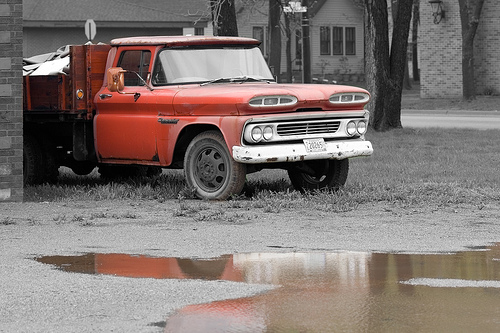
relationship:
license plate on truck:
[299, 136, 334, 156] [20, 26, 393, 218]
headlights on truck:
[239, 120, 368, 142] [20, 26, 393, 218]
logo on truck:
[152, 113, 188, 127] [20, 26, 393, 218]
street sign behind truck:
[80, 16, 101, 41] [20, 26, 393, 218]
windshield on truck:
[150, 40, 277, 88] [20, 26, 393, 218]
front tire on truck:
[181, 126, 246, 203] [20, 26, 393, 218]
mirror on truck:
[103, 65, 155, 101] [20, 26, 393, 218]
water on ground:
[308, 257, 378, 315] [7, 202, 500, 332]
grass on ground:
[398, 124, 499, 204] [7, 202, 500, 332]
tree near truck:
[360, 2, 423, 133] [20, 26, 393, 218]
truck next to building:
[20, 26, 393, 218] [413, 2, 499, 104]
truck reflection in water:
[93, 254, 310, 283] [308, 257, 378, 315]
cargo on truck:
[25, 41, 71, 74] [20, 26, 393, 218]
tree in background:
[360, 2, 423, 133] [20, 2, 500, 46]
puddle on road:
[260, 248, 437, 327] [7, 202, 500, 332]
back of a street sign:
[91, 27, 96, 33] [81, 19, 97, 41]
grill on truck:
[276, 119, 343, 135] [20, 26, 393, 218]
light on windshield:
[172, 63, 199, 77] [150, 40, 277, 88]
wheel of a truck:
[289, 155, 354, 193] [20, 26, 393, 218]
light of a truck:
[345, 118, 358, 135] [20, 26, 393, 218]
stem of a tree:
[365, 68, 411, 133] [360, 2, 423, 133]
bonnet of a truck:
[102, 29, 266, 50] [20, 26, 393, 218]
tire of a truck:
[181, 126, 246, 203] [20, 26, 393, 218]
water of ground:
[308, 257, 378, 315] [7, 202, 500, 332]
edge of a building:
[455, 13, 468, 99] [413, 2, 499, 104]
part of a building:
[440, 49, 454, 63] [413, 2, 499, 104]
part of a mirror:
[110, 72, 117, 81] [103, 65, 155, 101]